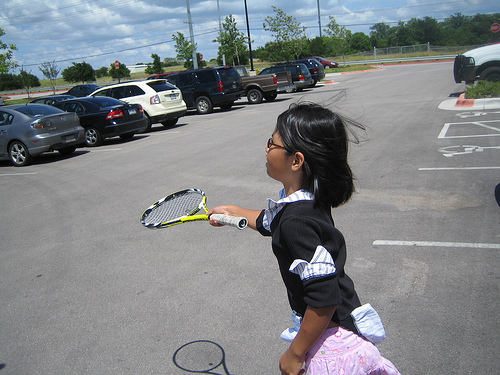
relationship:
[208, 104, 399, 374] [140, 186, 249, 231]
girl holding racket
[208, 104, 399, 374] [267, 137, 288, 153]
girl wearing glasses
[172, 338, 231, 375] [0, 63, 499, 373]
racket shadow on parking lot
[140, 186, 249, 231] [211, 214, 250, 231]
racket has white handle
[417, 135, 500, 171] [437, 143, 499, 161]
parking space for handicapped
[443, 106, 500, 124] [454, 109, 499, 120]
parking space for handicapped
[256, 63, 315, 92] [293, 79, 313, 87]
mini van has bumper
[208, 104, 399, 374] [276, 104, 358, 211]
girl has hair